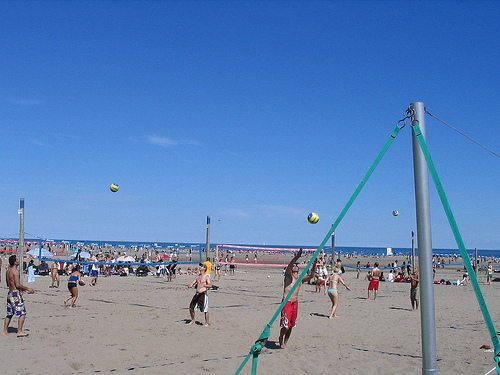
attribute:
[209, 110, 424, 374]
green strap —  tie, downs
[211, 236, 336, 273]
net — yellow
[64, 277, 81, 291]
bikini — black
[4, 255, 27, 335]
man — wearing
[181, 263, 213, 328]
man — shirtless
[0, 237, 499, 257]
ocean — Blue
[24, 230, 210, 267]
net — blue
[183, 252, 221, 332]
man — black, white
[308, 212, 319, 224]
volleyball — brightly colored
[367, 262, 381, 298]
people — playing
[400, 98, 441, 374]
pole — Silver, hold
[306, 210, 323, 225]
ball — white 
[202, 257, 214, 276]
shirt — yellow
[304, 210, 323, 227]
volleyball — blue, yellow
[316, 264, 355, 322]
woman — wearing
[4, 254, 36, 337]
trunks — white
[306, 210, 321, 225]
volleyball — playing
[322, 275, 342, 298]
bikini — green